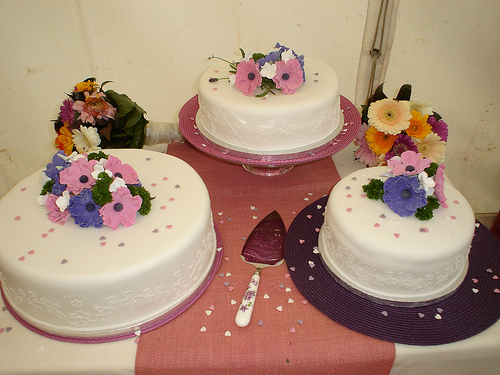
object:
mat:
[280, 193, 500, 345]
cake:
[317, 151, 476, 303]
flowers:
[417, 171, 435, 198]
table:
[0, 136, 500, 375]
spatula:
[234, 210, 286, 328]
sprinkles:
[348, 176, 459, 239]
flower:
[388, 149, 430, 178]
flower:
[382, 176, 427, 217]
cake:
[195, 57, 345, 156]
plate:
[178, 80, 362, 164]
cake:
[0, 148, 216, 341]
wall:
[0, 0, 500, 213]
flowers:
[368, 99, 413, 136]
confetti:
[289, 327, 297, 333]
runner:
[135, 142, 398, 375]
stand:
[244, 157, 294, 177]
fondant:
[344, 207, 352, 214]